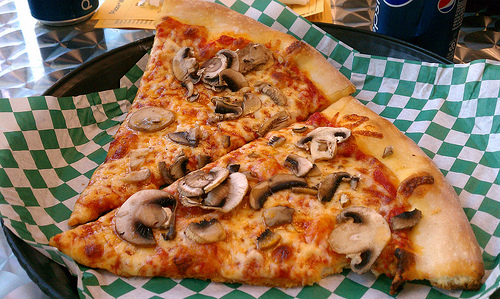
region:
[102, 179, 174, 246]
The pizza has a mushroom.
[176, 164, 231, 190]
The pizza has a mushroom.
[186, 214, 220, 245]
The pizza has a mushroom.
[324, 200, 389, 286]
The pizza has a mushroom.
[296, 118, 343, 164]
The pizza has a mushroom.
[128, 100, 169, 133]
The pizza has a mushroom.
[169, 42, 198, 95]
The pizza has a mushroom.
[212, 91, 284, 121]
The pizza has a mushroom.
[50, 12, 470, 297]
TWO SLICES OF PIZZA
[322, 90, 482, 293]
THE PIZZA CRUST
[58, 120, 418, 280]
THE CHEESE IS ON THE PIZZA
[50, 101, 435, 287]
THE MUSHROOMS ARE ON THE PIZZA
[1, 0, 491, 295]
THE PIZZA IS ON THE CHECKERED PAPER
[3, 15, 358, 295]
THE PLATE IS BLACK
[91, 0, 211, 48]
THE MENU IS YELLOW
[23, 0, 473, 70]
TWO DRINK CANS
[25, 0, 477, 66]
THE DRINK CANS ARE BLUE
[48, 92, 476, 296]
the slice of pizza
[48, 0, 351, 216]
the slice of pizza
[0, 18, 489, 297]
the paper under the pizza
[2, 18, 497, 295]
the paper is checkered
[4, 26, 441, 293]
the tray under the pizza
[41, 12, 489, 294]
the tray is black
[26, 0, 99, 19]
the can of soda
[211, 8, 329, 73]
the crust of the pizza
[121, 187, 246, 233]
mushrooms on the pizza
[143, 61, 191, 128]
melted cheese on the pizza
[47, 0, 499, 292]
two slices of pizza on a plate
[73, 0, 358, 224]
the slice of pizza has mushrooms on it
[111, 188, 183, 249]
this is a cooked mushroom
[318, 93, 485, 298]
the crust on a slice of pizza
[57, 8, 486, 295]
two slices of mushroom pizza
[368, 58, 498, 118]
green and white checkered parchment paper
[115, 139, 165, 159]
brown bubbly mozzarella cheese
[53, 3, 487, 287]
The slices are covered with brown bubbly cheese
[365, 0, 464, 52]
the bottom of a can of pepsi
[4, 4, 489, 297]
Two slices of pizza on a plate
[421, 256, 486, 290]
The end of a pizza crust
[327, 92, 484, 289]
The crust of a slice of pizza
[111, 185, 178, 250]
A slice of mushroom on a pizza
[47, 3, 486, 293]
Two pieces of cheese and mushroom pizza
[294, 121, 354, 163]
A slice of mushroom on a pizza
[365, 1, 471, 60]
Part of a soda can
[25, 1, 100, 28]
The bottom of a soda can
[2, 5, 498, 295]
A plate with checkered paper and pizza on it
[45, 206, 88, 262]
The tips of two slices of pizza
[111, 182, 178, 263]
A piece of food.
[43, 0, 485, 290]
Two pieces of pizza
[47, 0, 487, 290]
Two triangular pieces of pizza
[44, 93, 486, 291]
One triangular piece pizza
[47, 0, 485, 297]
Mushroom and cheese pizzas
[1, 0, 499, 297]
Pizzas on the green and white paper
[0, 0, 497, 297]
Black plate lined with green and white paper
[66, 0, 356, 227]
One triangular pizza with mushrooms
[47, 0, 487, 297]
Melted cheese on the pizza slices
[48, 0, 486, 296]
Mushrooms as toppings of pizzas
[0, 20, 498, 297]
Black disposable plate